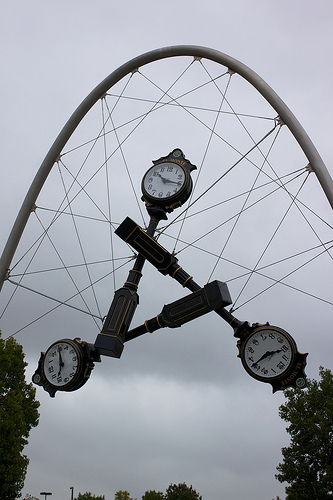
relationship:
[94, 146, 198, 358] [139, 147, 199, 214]
clock has clock face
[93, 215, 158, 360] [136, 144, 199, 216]
pole attached to clocks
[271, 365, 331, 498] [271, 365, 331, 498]
tree has leaves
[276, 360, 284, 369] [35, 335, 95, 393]
numbers on clock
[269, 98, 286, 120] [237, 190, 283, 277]
wall holding cables.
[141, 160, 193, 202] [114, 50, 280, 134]
clock hanging arch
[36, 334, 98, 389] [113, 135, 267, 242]
clock on top of pole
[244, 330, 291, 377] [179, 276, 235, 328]
clock on top of pole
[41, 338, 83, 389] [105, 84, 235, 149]
clock caught in web